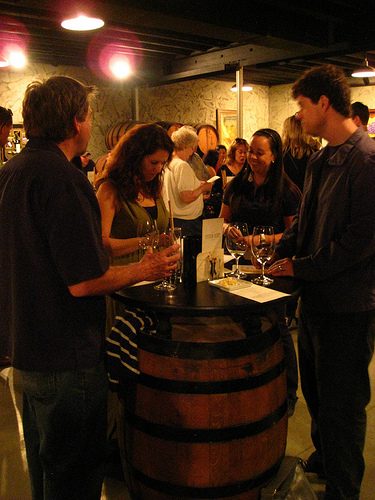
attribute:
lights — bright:
[64, 17, 104, 38]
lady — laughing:
[228, 121, 302, 256]